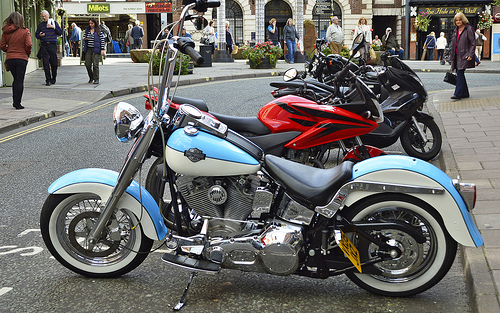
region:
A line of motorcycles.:
[38, 1, 483, 298]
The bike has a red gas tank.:
[257, 91, 379, 148]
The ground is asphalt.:
[2, 70, 499, 311]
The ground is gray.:
[2, 71, 499, 311]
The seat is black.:
[166, 95, 268, 136]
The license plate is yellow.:
[335, 230, 362, 271]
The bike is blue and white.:
[46, 104, 483, 249]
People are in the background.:
[33, 8, 145, 85]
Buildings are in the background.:
[51, 0, 498, 60]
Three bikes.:
[38, 2, 483, 299]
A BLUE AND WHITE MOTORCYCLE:
[36, 4, 487, 301]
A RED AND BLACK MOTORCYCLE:
[144, 69, 399, 164]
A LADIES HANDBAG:
[441, 65, 464, 90]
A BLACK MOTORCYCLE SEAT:
[261, 150, 353, 205]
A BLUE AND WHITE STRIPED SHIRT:
[80, 30, 107, 53]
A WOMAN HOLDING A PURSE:
[439, 11, 483, 103]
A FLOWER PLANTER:
[244, 36, 283, 72]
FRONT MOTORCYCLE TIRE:
[37, 190, 158, 280]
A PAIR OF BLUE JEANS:
[284, 36, 301, 67]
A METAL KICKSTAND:
[171, 265, 199, 311]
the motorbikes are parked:
[102, 18, 465, 301]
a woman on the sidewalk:
[446, 11, 486, 126]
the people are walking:
[5, 3, 130, 113]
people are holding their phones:
[6, 7, 128, 110]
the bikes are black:
[283, 26, 438, 137]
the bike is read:
[252, 75, 385, 169]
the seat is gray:
[252, 144, 371, 209]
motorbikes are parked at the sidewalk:
[62, 18, 449, 307]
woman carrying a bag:
[438, 25, 494, 109]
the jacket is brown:
[1, 23, 37, 60]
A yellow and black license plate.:
[334, 229, 363, 271]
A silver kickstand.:
[172, 272, 197, 309]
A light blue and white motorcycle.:
[39, 7, 485, 309]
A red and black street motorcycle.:
[140, 77, 387, 192]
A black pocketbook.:
[444, 68, 457, 85]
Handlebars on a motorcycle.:
[154, 0, 226, 110]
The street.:
[3, 73, 489, 311]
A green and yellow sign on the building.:
[87, 4, 109, 14]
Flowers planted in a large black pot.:
[247, 44, 277, 71]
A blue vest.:
[85, 22, 101, 52]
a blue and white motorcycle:
[41, 15, 492, 300]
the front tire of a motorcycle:
[23, 165, 165, 282]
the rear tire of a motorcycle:
[326, 187, 457, 295]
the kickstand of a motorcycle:
[159, 258, 206, 310]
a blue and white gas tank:
[164, 125, 264, 195]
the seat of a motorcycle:
[259, 147, 354, 202]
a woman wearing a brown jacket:
[1, 8, 33, 113]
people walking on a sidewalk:
[3, 0, 107, 110]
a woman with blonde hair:
[437, 10, 484, 107]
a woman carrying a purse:
[435, 3, 481, 103]